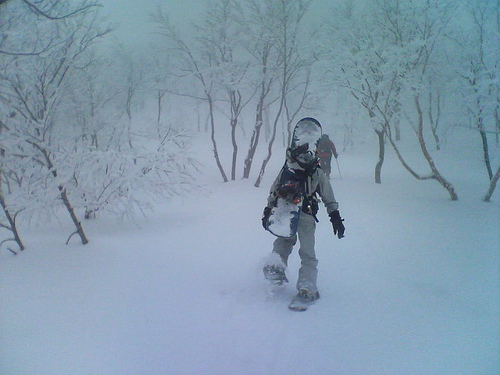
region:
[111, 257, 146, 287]
white snow on ground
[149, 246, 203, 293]
white snow on ground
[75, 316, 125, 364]
white snow on ground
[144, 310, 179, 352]
white snow on ground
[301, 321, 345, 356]
white snow on ground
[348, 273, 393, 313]
white snow on ground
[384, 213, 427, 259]
white snow on ground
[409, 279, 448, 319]
white snow on ground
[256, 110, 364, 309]
a man in the ice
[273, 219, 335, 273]
legs of the person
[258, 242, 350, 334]
shoe of the person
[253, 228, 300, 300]
shoe of the person covered with ice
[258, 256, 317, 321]
leg of the person covered with ice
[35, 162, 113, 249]
a tree in the ice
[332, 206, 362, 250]
gloves of the person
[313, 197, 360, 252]
hand of the person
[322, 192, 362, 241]
man wearing the gloves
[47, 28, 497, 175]
a group of trees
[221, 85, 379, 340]
people walking in heavy snow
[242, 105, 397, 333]
snowboarder and skier trekking through snow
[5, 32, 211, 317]
very heavy snow covering trees and ground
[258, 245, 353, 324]
snow building up on snow shoes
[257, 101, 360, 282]
snow building up on snowboard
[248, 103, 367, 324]
people backpacking in snow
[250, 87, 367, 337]
people backpacking through heavy snow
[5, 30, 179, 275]
heavy snow piled up on tree branches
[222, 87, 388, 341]
two people walking through snowy woods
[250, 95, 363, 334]
a person walking through the snow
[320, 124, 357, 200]
a person cross country skiing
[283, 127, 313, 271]
snowboard on persons back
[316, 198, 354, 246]
the ski glove of the person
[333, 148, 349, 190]
the ski pole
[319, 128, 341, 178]
person wearing a red ski jacket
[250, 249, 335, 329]
person wearing snow shoes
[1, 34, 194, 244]
trees covered with fresh fallen snow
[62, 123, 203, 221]
the snow covered branches of a small tree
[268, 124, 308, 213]
man is carrying snowboard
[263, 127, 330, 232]
board is black and white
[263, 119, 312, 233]
snow covers snowboard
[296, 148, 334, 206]
man has grey shirt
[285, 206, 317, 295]
man has grey pants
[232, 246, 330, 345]
man is tracking through snow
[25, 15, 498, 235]
white trees around men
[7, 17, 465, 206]
snow is covering trees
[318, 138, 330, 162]
man has red coat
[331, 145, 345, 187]
man holds ski pole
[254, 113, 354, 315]
a man in white wearing snow shoes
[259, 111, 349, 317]
person with a snow board on his back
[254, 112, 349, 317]
person carrying snowboard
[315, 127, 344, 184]
a person with ski poles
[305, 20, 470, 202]
a tree covered in snow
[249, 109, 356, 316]
man cover in snow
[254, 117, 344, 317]
man cover in white snow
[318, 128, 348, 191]
man in red jacket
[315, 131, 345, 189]
man in red jacket sking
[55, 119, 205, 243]
tree branches cover in snow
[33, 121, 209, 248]
tree branches cover in white snow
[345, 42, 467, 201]
tree branches cover in snow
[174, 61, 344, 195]
tree branches cover in white snow